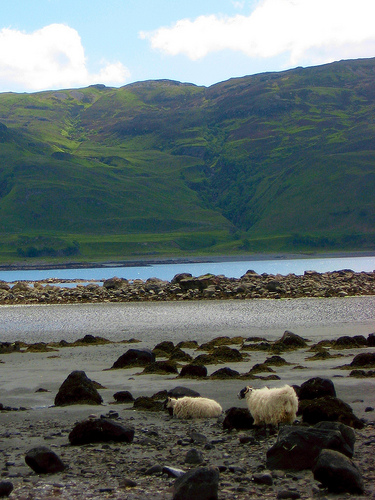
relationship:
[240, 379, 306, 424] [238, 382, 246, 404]
animal has horns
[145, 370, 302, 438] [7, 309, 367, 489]
animals sitting on beach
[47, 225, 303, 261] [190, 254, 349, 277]
grass behind water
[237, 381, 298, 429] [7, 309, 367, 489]
animal on beach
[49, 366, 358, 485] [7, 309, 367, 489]
rocks on beach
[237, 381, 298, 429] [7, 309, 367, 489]
animal are standing on beach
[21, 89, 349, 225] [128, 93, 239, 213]
mountain has valleys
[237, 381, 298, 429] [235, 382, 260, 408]
animal has head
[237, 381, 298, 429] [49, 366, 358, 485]
animal are among rocks